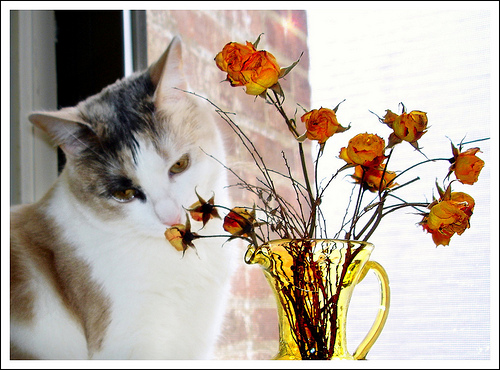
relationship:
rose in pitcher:
[295, 98, 341, 248] [243, 238, 391, 359]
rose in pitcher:
[344, 183, 480, 245] [243, 238, 391, 359]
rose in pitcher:
[343, 134, 487, 237] [243, 238, 391, 359]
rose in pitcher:
[162, 213, 265, 247] [243, 238, 391, 359]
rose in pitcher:
[222, 204, 272, 244] [243, 238, 391, 359]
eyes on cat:
[167, 152, 191, 179] [9, 36, 220, 357]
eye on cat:
[102, 174, 135, 194] [9, 36, 220, 357]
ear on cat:
[25, 107, 94, 153] [7, 35, 240, 362]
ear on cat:
[145, 36, 186, 102] [7, 35, 240, 362]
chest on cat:
[92, 196, 234, 360] [7, 35, 240, 362]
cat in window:
[9, 36, 220, 357] [305, 0, 495, 362]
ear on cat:
[145, 32, 186, 102] [9, 36, 220, 357]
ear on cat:
[25, 111, 94, 153] [9, 36, 220, 357]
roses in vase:
[164, 33, 484, 247] [241, 233, 392, 358]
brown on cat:
[15, 205, 59, 264] [7, 35, 240, 362]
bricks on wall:
[148, 10, 307, 89] [144, 10, 314, 360]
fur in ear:
[9, 34, 244, 363] [24, 109, 94, 147]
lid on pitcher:
[246, 234, 378, 267] [243, 238, 391, 360]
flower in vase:
[338, 131, 389, 169] [241, 233, 392, 358]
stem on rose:
[198, 198, 251, 229] [441, 135, 486, 185]